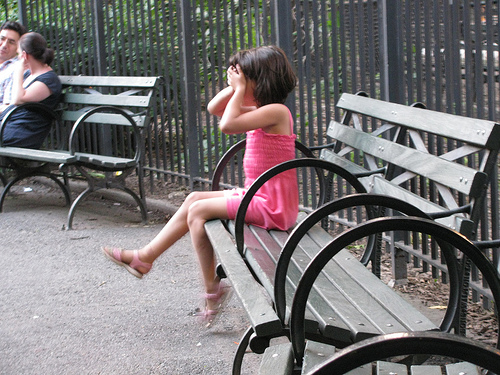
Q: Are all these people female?
A: No, they are both male and female.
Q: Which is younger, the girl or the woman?
A: The girl is younger than the woman.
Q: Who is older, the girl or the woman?
A: The woman is older than the girl.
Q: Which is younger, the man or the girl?
A: The girl is younger than the man.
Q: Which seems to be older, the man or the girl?
A: The man is older than the girl.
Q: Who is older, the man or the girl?
A: The man is older than the girl.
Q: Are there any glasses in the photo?
A: No, there are no glasses.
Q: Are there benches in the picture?
A: Yes, there is a bench.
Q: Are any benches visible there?
A: Yes, there is a bench.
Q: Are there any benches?
A: Yes, there is a bench.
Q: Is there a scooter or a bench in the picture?
A: Yes, there is a bench.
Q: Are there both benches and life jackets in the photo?
A: No, there is a bench but no life jackets.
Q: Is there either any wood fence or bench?
A: Yes, there is a wood bench.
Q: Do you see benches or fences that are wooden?
A: Yes, the bench is wooden.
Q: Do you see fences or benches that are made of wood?
A: Yes, the bench is made of wood.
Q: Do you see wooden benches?
A: Yes, there is a wood bench.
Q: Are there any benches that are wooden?
A: Yes, there is a bench that is wooden.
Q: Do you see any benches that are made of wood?
A: Yes, there is a bench that is made of wood.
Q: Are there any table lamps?
A: No, there are no table lamps.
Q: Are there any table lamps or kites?
A: No, there are no table lamps or kites.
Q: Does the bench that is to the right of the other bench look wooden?
A: Yes, the bench is wooden.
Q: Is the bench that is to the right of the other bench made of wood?
A: Yes, the bench is made of wood.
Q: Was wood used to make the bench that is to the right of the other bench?
A: Yes, the bench is made of wood.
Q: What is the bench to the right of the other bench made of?
A: The bench is made of wood.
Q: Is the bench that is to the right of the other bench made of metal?
A: No, the bench is made of wood.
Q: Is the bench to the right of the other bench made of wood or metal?
A: The bench is made of wood.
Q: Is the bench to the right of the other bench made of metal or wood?
A: The bench is made of wood.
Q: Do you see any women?
A: Yes, there is a woman.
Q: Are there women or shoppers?
A: Yes, there is a woman.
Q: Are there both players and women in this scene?
A: No, there is a woman but no players.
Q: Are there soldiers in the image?
A: No, there are no soldiers.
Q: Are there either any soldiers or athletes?
A: No, there are no soldiers or athletes.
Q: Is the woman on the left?
A: Yes, the woman is on the left of the image.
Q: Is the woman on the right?
A: No, the woman is on the left of the image.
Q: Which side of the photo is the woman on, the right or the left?
A: The woman is on the left of the image.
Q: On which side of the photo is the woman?
A: The woman is on the left of the image.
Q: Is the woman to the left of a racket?
A: No, the woman is to the left of the fence.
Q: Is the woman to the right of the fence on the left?
A: No, the woman is to the left of the fence.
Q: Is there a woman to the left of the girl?
A: Yes, there is a woman to the left of the girl.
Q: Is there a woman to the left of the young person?
A: Yes, there is a woman to the left of the girl.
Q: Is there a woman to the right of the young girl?
A: No, the woman is to the left of the girl.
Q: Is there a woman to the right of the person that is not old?
A: No, the woman is to the left of the girl.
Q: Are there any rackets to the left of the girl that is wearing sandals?
A: No, there is a woman to the left of the girl.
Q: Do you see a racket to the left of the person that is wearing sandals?
A: No, there is a woman to the left of the girl.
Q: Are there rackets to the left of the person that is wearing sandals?
A: No, there is a woman to the left of the girl.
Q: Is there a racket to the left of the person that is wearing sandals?
A: No, there is a woman to the left of the girl.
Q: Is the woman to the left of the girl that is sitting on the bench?
A: Yes, the woman is to the left of the girl.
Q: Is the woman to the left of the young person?
A: Yes, the woman is to the left of the girl.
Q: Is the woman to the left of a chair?
A: No, the woman is to the left of the girl.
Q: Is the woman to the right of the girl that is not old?
A: No, the woman is to the left of the girl.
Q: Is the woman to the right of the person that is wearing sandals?
A: No, the woman is to the left of the girl.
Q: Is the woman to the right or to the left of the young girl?
A: The woman is to the left of the girl.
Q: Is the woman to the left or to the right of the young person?
A: The woman is to the left of the girl.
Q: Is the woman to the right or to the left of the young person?
A: The woman is to the left of the girl.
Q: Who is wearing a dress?
A: The woman is wearing a dress.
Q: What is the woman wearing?
A: The woman is wearing a dress.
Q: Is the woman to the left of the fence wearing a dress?
A: Yes, the woman is wearing a dress.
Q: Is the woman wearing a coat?
A: No, the woman is wearing a dress.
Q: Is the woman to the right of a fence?
A: No, the woman is to the left of a fence.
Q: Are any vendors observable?
A: No, there are no vendors.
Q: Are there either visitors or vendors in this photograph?
A: No, there are no vendors or visitors.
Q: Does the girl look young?
A: Yes, the girl is young.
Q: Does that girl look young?
A: Yes, the girl is young.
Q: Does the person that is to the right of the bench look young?
A: Yes, the girl is young.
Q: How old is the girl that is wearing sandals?
A: The girl is young.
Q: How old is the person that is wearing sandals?
A: The girl is young.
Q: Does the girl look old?
A: No, the girl is young.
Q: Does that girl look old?
A: No, the girl is young.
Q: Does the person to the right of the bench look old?
A: No, the girl is young.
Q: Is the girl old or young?
A: The girl is young.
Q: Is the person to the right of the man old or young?
A: The girl is young.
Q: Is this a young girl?
A: Yes, this is a young girl.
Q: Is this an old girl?
A: No, this is a young girl.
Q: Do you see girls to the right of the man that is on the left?
A: Yes, there is a girl to the right of the man.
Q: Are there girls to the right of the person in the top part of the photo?
A: Yes, there is a girl to the right of the man.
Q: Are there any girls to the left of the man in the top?
A: No, the girl is to the right of the man.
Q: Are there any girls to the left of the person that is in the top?
A: No, the girl is to the right of the man.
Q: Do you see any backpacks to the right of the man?
A: No, there is a girl to the right of the man.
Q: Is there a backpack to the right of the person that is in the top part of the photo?
A: No, there is a girl to the right of the man.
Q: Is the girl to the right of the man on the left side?
A: Yes, the girl is to the right of the man.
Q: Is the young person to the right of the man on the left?
A: Yes, the girl is to the right of the man.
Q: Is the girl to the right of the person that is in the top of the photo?
A: Yes, the girl is to the right of the man.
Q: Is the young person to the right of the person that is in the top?
A: Yes, the girl is to the right of the man.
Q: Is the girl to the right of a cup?
A: No, the girl is to the right of the man.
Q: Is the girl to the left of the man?
A: No, the girl is to the right of the man.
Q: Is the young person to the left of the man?
A: No, the girl is to the right of the man.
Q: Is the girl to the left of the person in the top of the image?
A: No, the girl is to the right of the man.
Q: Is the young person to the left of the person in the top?
A: No, the girl is to the right of the man.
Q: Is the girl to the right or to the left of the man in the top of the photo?
A: The girl is to the right of the man.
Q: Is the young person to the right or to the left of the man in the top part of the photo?
A: The girl is to the right of the man.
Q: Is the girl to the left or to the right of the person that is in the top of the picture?
A: The girl is to the right of the man.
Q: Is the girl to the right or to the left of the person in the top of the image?
A: The girl is to the right of the man.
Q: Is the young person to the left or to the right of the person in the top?
A: The girl is to the right of the man.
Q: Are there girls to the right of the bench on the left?
A: Yes, there is a girl to the right of the bench.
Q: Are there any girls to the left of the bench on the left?
A: No, the girl is to the right of the bench.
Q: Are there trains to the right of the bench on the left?
A: No, there is a girl to the right of the bench.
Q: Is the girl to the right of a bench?
A: Yes, the girl is to the right of a bench.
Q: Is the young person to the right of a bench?
A: Yes, the girl is to the right of a bench.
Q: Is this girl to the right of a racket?
A: No, the girl is to the right of a bench.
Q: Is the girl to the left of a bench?
A: No, the girl is to the right of a bench.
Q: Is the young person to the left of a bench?
A: No, the girl is to the right of a bench.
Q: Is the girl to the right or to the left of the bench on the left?
A: The girl is to the right of the bench.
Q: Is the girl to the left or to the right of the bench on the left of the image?
A: The girl is to the right of the bench.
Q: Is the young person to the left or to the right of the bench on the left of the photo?
A: The girl is to the right of the bench.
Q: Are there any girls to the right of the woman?
A: Yes, there is a girl to the right of the woman.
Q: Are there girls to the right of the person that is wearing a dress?
A: Yes, there is a girl to the right of the woman.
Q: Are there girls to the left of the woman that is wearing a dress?
A: No, the girl is to the right of the woman.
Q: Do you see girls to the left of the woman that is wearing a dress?
A: No, the girl is to the right of the woman.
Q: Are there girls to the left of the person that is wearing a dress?
A: No, the girl is to the right of the woman.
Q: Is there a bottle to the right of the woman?
A: No, there is a girl to the right of the woman.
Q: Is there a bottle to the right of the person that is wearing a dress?
A: No, there is a girl to the right of the woman.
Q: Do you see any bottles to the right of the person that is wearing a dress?
A: No, there is a girl to the right of the woman.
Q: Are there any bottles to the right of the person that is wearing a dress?
A: No, there is a girl to the right of the woman.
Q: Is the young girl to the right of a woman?
A: Yes, the girl is to the right of a woman.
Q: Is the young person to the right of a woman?
A: Yes, the girl is to the right of a woman.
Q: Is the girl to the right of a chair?
A: No, the girl is to the right of a woman.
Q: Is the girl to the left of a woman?
A: No, the girl is to the right of a woman.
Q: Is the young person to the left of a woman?
A: No, the girl is to the right of a woman.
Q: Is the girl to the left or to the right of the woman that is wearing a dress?
A: The girl is to the right of the woman.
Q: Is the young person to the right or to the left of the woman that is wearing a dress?
A: The girl is to the right of the woman.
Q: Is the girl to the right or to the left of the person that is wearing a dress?
A: The girl is to the right of the woman.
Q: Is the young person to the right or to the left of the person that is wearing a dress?
A: The girl is to the right of the woman.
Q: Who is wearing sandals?
A: The girl is wearing sandals.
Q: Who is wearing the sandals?
A: The girl is wearing sandals.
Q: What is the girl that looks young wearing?
A: The girl is wearing sandals.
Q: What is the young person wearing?
A: The girl is wearing sandals.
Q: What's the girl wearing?
A: The girl is wearing sandals.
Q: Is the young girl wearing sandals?
A: Yes, the girl is wearing sandals.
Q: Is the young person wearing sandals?
A: Yes, the girl is wearing sandals.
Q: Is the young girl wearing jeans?
A: No, the girl is wearing sandals.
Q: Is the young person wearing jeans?
A: No, the girl is wearing sandals.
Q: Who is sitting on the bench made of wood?
A: The girl is sitting on the bench.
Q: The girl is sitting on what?
A: The girl is sitting on the bench.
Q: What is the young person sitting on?
A: The girl is sitting on the bench.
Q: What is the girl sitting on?
A: The girl is sitting on the bench.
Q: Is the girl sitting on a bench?
A: Yes, the girl is sitting on a bench.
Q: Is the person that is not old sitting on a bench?
A: Yes, the girl is sitting on a bench.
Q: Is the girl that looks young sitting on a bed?
A: No, the girl is sitting on a bench.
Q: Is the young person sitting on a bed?
A: No, the girl is sitting on a bench.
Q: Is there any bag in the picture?
A: No, there are no bags.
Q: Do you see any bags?
A: No, there are no bags.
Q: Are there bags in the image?
A: No, there are no bags.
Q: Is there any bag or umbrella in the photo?
A: No, there are no bags or umbrellas.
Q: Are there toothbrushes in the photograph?
A: No, there are no toothbrushes.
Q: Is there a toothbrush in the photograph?
A: No, there are no toothbrushes.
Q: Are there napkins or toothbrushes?
A: No, there are no toothbrushes or napkins.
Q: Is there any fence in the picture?
A: Yes, there is a fence.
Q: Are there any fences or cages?
A: Yes, there is a fence.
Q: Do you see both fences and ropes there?
A: No, there is a fence but no ropes.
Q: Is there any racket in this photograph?
A: No, there are no rackets.